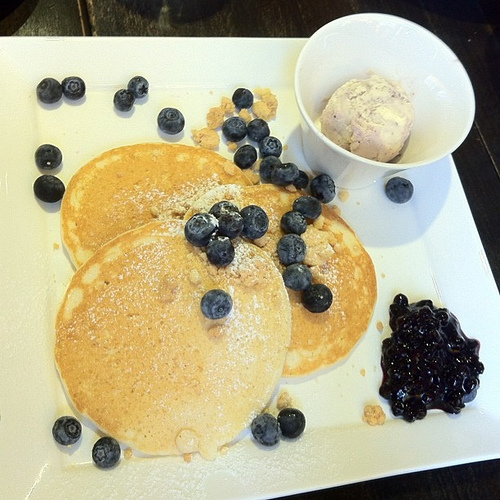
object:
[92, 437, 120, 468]
blueberry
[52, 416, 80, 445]
blueberry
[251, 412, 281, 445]
blueberry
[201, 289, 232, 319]
blueberry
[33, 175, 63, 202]
blueberry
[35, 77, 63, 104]
blueberries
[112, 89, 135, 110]
blueberries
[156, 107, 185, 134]
blueberries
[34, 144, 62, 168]
blueberries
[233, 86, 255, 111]
blueberries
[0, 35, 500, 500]
dish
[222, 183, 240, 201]
sugar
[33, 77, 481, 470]
food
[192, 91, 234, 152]
sugar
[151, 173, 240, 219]
sugar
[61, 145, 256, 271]
pancake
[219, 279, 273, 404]
sugar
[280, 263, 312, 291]
blueberries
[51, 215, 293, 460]
pancake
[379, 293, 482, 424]
blueberries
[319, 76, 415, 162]
butter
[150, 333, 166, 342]
holes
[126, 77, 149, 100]
berries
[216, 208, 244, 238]
blueberries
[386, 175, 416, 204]
blueberry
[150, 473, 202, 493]
sugar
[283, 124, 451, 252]
shadow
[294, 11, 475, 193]
bowl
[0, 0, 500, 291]
boards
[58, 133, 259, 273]
pancakes